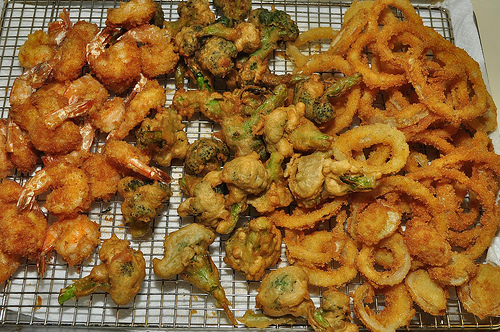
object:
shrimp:
[144, 28, 173, 78]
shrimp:
[99, 32, 146, 79]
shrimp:
[116, 143, 145, 174]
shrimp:
[34, 155, 83, 214]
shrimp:
[51, 214, 95, 262]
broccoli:
[56, 232, 147, 310]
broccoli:
[149, 220, 244, 328]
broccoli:
[114, 175, 174, 241]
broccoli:
[193, 16, 264, 56]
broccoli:
[291, 72, 365, 125]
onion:
[354, 283, 409, 331]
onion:
[413, 277, 439, 314]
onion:
[359, 244, 407, 284]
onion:
[474, 264, 497, 320]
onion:
[355, 39, 372, 77]